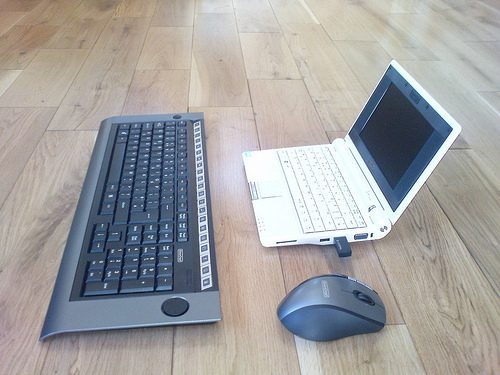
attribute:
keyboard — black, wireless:
[40, 113, 223, 340]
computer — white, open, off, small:
[241, 57, 464, 247]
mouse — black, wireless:
[276, 272, 387, 343]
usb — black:
[335, 237, 352, 258]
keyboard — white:
[277, 148, 368, 234]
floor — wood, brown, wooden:
[1, 2, 498, 374]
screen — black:
[359, 79, 436, 190]